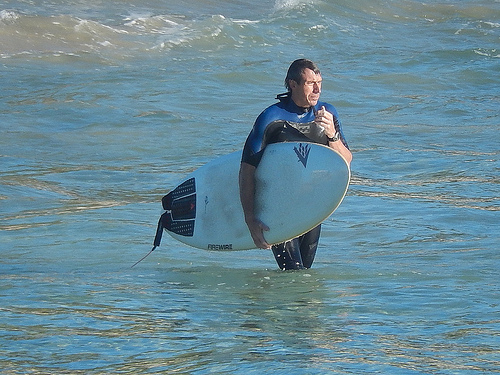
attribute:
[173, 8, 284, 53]
wave — white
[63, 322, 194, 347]
wave — white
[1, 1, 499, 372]
waters — blue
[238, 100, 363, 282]
wetsuit — black, blue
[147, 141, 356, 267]
surfboard — white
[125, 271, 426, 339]
waves — white, gray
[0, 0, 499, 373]
waves — white, gray, grey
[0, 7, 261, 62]
ocean waves — white, gray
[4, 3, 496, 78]
waves — white, gray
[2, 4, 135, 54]
wave — white, gray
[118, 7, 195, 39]
wave — gray